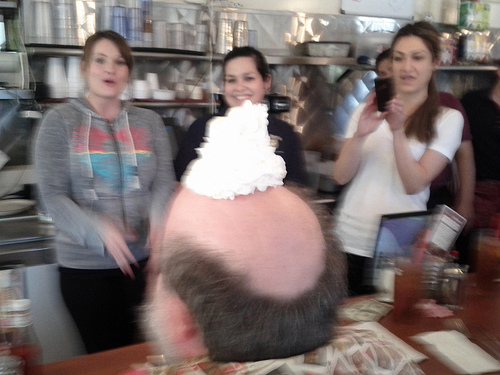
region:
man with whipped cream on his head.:
[132, 84, 387, 371]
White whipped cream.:
[151, 82, 338, 211]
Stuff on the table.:
[372, 178, 499, 305]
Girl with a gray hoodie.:
[24, 17, 213, 327]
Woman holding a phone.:
[343, 41, 456, 169]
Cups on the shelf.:
[130, 28, 235, 120]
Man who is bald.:
[139, 125, 370, 357]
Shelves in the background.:
[252, 13, 409, 104]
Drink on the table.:
[368, 231, 445, 341]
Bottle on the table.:
[5, 294, 63, 374]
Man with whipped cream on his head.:
[165, 76, 367, 250]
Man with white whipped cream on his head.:
[126, 66, 313, 223]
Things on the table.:
[358, 172, 482, 317]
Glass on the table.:
[356, 242, 465, 325]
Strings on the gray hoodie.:
[58, 47, 190, 278]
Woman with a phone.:
[313, 17, 430, 177]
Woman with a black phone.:
[356, 41, 390, 118]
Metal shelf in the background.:
[219, 10, 387, 87]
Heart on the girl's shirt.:
[48, 77, 174, 183]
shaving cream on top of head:
[176, 87, 294, 197]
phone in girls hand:
[366, 69, 397, 123]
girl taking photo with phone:
[363, 17, 438, 272]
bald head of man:
[181, 189, 345, 329]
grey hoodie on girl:
[64, 114, 164, 273]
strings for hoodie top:
[68, 112, 143, 201]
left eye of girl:
[413, 47, 428, 65]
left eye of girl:
[242, 69, 257, 86]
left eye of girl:
[111, 52, 131, 69]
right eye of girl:
[387, 48, 405, 63]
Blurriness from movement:
[18, 45, 170, 322]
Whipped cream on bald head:
[88, 68, 384, 365]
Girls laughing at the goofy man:
[42, 8, 456, 355]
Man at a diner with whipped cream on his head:
[11, 63, 466, 374]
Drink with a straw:
[363, 206, 449, 336]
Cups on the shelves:
[33, 3, 232, 100]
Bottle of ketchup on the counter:
[0, 274, 75, 372]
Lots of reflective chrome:
[230, 6, 397, 203]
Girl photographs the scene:
[178, 15, 451, 339]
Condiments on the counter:
[377, 242, 485, 312]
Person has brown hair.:
[398, 22, 457, 129]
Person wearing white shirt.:
[351, 147, 405, 214]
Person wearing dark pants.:
[344, 245, 375, 306]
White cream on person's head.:
[188, 128, 253, 194]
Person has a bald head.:
[228, 200, 301, 282]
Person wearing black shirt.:
[278, 131, 313, 188]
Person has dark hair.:
[254, 62, 290, 91]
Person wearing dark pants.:
[92, 283, 115, 322]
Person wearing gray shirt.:
[63, 145, 141, 214]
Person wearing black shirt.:
[483, 103, 494, 135]